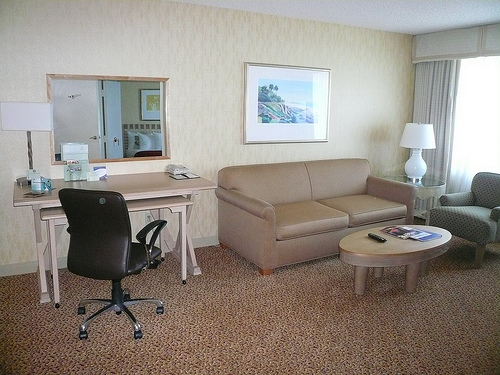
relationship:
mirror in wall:
[46, 72, 170, 168] [0, 0, 417, 278]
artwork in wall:
[241, 60, 328, 143] [0, 0, 417, 278]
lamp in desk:
[1, 103, 55, 184] [10, 170, 215, 304]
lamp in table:
[398, 122, 436, 180] [384, 174, 447, 226]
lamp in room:
[398, 122, 436, 180] [8, 7, 489, 373]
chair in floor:
[58, 187, 167, 337] [2, 217, 497, 371]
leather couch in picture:
[213, 158, 419, 275] [234, 52, 344, 152]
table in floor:
[338, 222, 452, 298] [2, 236, 497, 373]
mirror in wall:
[46, 72, 170, 168] [18, 9, 236, 109]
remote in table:
[368, 230, 388, 243] [338, 222, 452, 298]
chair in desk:
[58, 187, 168, 337] [10, 170, 213, 305]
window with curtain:
[448, 54, 498, 189] [399, 57, 460, 215]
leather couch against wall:
[213, 158, 419, 275] [0, 0, 417, 278]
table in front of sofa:
[338, 222, 452, 295] [212, 156, 416, 276]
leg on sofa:
[256, 266, 278, 278] [212, 156, 416, 276]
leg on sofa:
[216, 236, 229, 252] [212, 156, 416, 276]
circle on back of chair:
[97, 197, 107, 204] [58, 187, 168, 337]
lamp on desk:
[1, 103, 56, 184] [10, 170, 213, 305]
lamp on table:
[398, 122, 436, 180] [386, 172, 447, 224]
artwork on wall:
[241, 60, 328, 143] [39, 3, 406, 201]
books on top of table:
[382, 222, 414, 239] [334, 217, 459, 304]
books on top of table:
[405, 225, 439, 242] [334, 217, 459, 304]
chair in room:
[58, 187, 168, 337] [8, 7, 489, 373]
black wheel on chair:
[155, 305, 165, 315] [28, 168, 193, 370]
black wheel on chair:
[134, 329, 143, 339] [28, 168, 193, 370]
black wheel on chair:
[79, 330, 88, 341] [28, 168, 193, 370]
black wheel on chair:
[75, 305, 86, 314] [28, 168, 193, 370]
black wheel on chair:
[122, 293, 131, 300] [28, 168, 193, 370]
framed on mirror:
[46, 72, 175, 166] [46, 72, 170, 168]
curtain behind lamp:
[403, 57, 461, 215] [398, 122, 436, 180]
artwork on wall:
[238, 60, 329, 143] [2, 2, 493, 267]